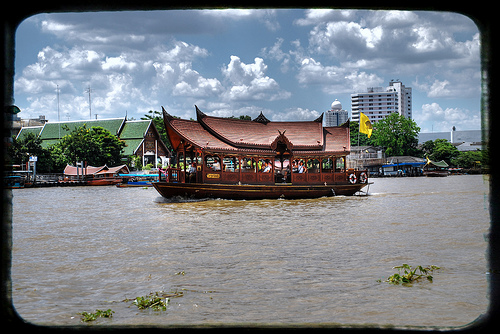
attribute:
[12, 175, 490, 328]
water — calm, brown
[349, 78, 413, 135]
building — white, tall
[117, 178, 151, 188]
boat — small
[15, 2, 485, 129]
clouds — gray, fluffy, white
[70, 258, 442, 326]
plants — green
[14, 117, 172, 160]
roof — green, pointy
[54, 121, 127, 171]
tree — green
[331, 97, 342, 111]
top — round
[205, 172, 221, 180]
plaque — yellow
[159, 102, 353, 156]
roof — brown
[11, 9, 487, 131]
sky — clear, blue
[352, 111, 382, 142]
flag — yellow, small, waving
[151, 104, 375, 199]
boat — wood, brown